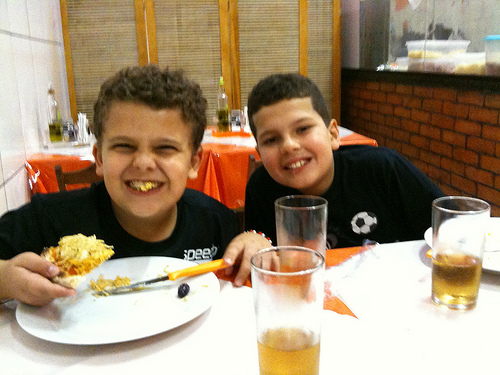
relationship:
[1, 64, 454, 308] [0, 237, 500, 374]
boys at table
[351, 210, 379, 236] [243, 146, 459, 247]
ball on shirt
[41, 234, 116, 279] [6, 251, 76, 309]
food in hand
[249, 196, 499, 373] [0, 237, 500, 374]
glasses on table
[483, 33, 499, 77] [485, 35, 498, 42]
container has lid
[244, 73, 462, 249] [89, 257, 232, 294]
boy holding knife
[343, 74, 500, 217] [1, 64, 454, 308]
wall behind boys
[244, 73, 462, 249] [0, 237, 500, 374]
boy at table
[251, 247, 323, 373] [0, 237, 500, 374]
glass on table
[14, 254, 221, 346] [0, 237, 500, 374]
plate on table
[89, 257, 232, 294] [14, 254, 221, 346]
knife on plate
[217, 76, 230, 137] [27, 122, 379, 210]
bottle on table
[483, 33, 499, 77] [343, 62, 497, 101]
container on table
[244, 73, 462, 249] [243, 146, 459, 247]
boy wearing shirt